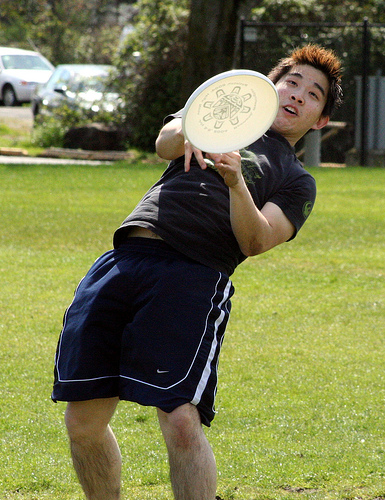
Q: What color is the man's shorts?
A: Navy blue.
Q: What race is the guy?
A: Asian.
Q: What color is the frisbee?
A: White.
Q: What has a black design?
A: White frisbee.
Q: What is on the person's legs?
A: Hair.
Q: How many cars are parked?
A: Two.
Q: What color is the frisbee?
A: White.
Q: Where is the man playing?
A: On grass.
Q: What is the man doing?
A: Playing frisbee.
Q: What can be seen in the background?
A: Cars.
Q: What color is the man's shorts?
A: Blue.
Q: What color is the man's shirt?
A: Black.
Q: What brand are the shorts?
A: Nike.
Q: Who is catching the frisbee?
A: The man.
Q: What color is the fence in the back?
A: Black.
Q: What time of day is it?
A: It is daytime.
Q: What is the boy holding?
A: Plate.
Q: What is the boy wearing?
A: Shorts.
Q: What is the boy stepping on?
A: Grass.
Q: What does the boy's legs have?
A: Black hair.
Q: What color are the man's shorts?
A: Blue.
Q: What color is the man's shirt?
A: Blue.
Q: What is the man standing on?
A: Ground.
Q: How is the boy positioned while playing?
A: Bent.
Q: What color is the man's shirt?
A: Blue.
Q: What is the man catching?
A: A frisbee.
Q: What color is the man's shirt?
A: Black.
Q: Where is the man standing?
A: On the grass.